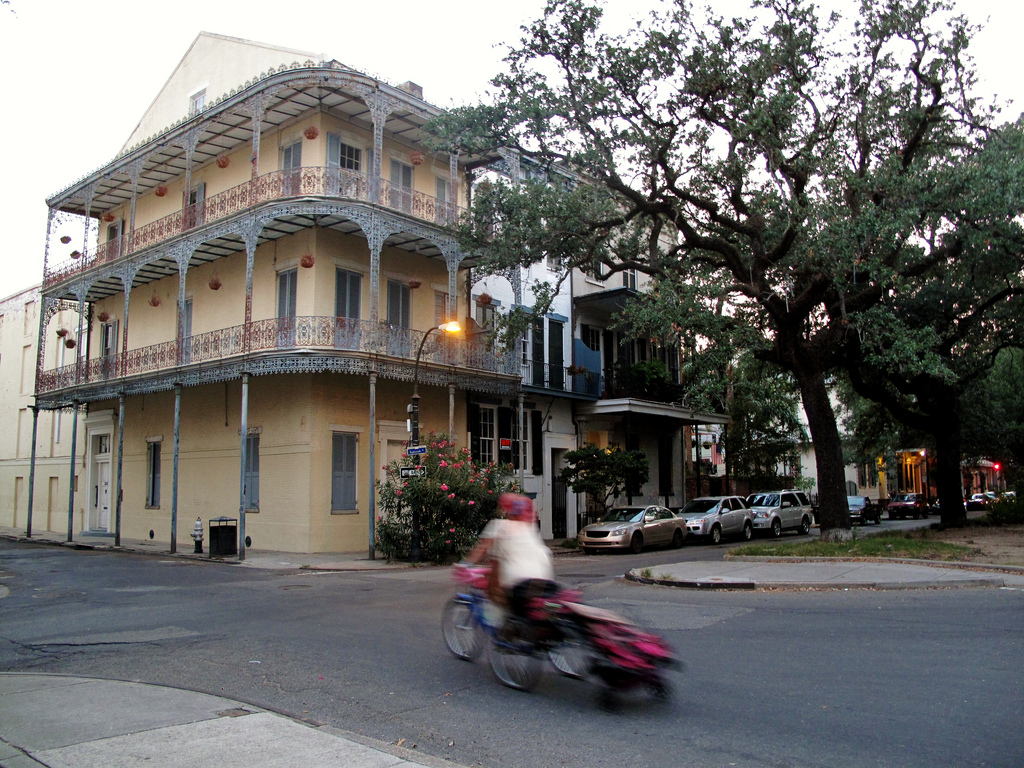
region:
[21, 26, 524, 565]
a three story house with balconies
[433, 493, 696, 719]
a small person on a tricycle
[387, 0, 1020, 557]
a large tree beside the road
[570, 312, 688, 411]
an exterior wall that is blue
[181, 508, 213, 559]
a hydrant on the far sidewalk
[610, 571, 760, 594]
the openings of a storm sewer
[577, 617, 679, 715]
a trailer being pulled by a tricycle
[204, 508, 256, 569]
Small opening on the side of the building.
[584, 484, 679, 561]
Silver car parked on the side of the road.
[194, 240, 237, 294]
Small red ball hanging from the ceiling.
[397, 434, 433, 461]
Sign on the side of the pole.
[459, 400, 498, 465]
Black frame on the side of the window.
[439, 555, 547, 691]
Person riding a blue bike.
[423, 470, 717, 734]
man drive a motorcycle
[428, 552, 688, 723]
the motorcycle is red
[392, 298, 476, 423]
a light outside the street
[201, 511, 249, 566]
a trash can on next the pole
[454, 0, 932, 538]
the tree is big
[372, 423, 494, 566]
plant with red flowers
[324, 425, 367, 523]
the window is gray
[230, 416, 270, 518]
the window is gray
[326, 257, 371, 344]
the window is gray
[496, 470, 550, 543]
hat wearing by girl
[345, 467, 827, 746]
a cycle in the road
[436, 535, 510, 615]
cloth on the cycle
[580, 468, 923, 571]
cars near the building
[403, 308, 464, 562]
streetlight lit up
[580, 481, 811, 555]
cars on the street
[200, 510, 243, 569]
trashcan sitting on the street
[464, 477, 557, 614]
person wearing a helmet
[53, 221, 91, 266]
decorations hanging from the ceiling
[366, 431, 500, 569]
rose bush next to a building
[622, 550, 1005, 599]
curb sitting by the street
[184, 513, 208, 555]
fire hydrant by the curb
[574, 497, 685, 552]
gold car parked in street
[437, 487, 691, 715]
person on a motorcycle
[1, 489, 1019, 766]
motorcycle going down the street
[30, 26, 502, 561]
large cream-colored house on a corner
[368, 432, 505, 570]
bush with pink flowers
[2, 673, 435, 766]
cement sidewalk beside a roadway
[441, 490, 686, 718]
person riding a bike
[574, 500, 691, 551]
small tan car parked on the street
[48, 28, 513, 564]
large building with two balconies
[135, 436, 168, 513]
window on a building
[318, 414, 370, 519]
window on a building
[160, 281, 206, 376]
window on a building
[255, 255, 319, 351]
window on a building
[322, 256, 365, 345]
window on a building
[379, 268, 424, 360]
window on a building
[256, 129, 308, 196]
window on a building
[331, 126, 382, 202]
window on a building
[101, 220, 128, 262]
window of multi story house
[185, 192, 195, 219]
window of multi story house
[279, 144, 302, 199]
window of multi story house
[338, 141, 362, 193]
window of multi story house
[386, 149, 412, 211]
window of multi story house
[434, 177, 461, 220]
window of multi story house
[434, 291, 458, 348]
window of multi story house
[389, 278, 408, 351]
window of multi story house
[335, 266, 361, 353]
window of multi story house